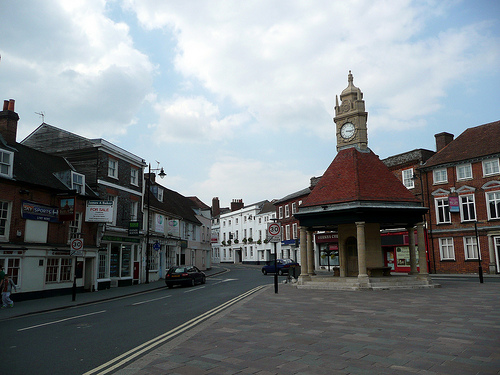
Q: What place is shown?
A: It is a city.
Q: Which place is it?
A: It is a city.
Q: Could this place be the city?
A: Yes, it is the city.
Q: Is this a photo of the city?
A: Yes, it is showing the city.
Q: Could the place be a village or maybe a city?
A: It is a city.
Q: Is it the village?
A: No, it is the city.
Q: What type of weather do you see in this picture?
A: It is cloudy.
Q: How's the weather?
A: It is cloudy.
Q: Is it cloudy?
A: Yes, it is cloudy.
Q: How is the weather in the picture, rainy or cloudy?
A: It is cloudy.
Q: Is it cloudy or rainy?
A: It is cloudy.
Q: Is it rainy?
A: No, it is cloudy.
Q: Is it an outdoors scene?
A: Yes, it is outdoors.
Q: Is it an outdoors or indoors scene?
A: It is outdoors.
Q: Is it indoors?
A: No, it is outdoors.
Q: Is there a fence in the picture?
A: No, there are no fences.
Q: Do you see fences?
A: No, there are no fences.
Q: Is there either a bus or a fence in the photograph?
A: No, there are no fences or buses.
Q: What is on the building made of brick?
A: The sign is on the building.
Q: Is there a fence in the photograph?
A: No, there are no fences.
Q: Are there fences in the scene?
A: No, there are no fences.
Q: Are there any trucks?
A: No, there are no trucks.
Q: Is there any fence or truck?
A: No, there are no trucks or fences.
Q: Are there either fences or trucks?
A: No, there are no trucks or fences.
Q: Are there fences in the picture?
A: No, there are no fences.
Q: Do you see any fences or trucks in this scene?
A: No, there are no fences or trucks.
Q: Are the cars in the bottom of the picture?
A: Yes, the cars are in the bottom of the image.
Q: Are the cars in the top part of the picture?
A: No, the cars are in the bottom of the image.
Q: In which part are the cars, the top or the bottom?
A: The cars are in the bottom of the image.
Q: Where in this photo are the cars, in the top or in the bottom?
A: The cars are in the bottom of the image.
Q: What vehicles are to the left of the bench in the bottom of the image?
A: The vehicles are cars.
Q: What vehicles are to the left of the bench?
A: The vehicles are cars.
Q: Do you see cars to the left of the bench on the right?
A: Yes, there are cars to the left of the bench.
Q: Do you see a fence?
A: No, there are no fences.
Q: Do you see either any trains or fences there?
A: No, there are no fences or trains.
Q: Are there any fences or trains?
A: No, there are no fences or trains.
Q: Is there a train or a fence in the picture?
A: No, there are no fences or trains.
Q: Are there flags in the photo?
A: No, there are no flags.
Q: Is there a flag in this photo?
A: No, there are no flags.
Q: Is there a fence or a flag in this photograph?
A: No, there are no flags or fences.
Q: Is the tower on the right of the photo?
A: Yes, the tower is on the right of the image.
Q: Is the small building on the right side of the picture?
A: Yes, the tower is on the right of the image.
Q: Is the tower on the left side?
A: No, the tower is on the right of the image.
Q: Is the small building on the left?
A: No, the tower is on the right of the image.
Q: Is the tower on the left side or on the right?
A: The tower is on the right of the image.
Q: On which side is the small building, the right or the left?
A: The tower is on the right of the image.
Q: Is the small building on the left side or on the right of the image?
A: The tower is on the right of the image.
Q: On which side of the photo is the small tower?
A: The tower is on the right of the image.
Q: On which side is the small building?
A: The tower is on the right of the image.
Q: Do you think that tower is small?
A: Yes, the tower is small.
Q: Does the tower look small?
A: Yes, the tower is small.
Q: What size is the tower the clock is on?
A: The tower is small.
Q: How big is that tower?
A: The tower is small.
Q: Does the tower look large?
A: No, the tower is small.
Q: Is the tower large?
A: No, the tower is small.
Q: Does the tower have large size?
A: No, the tower is small.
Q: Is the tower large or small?
A: The tower is small.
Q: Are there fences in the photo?
A: No, there are no fences.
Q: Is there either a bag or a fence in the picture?
A: No, there are no fences or bags.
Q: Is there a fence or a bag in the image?
A: No, there are no fences or bags.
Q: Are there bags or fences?
A: No, there are no fences or bags.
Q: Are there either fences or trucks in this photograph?
A: No, there are no fences or trucks.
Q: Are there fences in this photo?
A: No, there are no fences.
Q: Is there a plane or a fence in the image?
A: No, there are no fences or airplanes.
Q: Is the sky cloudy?
A: Yes, the sky is cloudy.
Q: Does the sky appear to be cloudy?
A: Yes, the sky is cloudy.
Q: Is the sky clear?
A: No, the sky is cloudy.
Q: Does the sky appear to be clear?
A: No, the sky is cloudy.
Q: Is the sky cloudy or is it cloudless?
A: The sky is cloudy.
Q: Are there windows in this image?
A: Yes, there are windows.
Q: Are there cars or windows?
A: Yes, there are windows.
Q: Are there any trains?
A: No, there are no trains.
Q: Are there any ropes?
A: No, there are no ropes.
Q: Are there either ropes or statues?
A: No, there are no ropes or statues.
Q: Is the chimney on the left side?
A: Yes, the chimney is on the left of the image.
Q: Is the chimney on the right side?
A: No, the chimney is on the left of the image.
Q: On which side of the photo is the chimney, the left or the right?
A: The chimney is on the left of the image.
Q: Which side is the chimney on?
A: The chimney is on the left of the image.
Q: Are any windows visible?
A: Yes, there are windows.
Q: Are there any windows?
A: Yes, there are windows.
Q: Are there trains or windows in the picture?
A: Yes, there are windows.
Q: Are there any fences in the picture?
A: No, there are no fences.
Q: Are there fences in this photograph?
A: No, there are no fences.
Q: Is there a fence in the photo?
A: No, there are no fences.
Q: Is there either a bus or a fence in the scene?
A: No, there are no fences or buses.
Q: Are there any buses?
A: No, there are no buses.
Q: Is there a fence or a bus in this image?
A: No, there are no buses or fences.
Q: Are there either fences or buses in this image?
A: No, there are no buses or fences.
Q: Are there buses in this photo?
A: No, there are no buses.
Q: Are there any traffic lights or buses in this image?
A: No, there are no buses or traffic lights.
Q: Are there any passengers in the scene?
A: No, there are no passengers.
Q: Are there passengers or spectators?
A: No, there are no passengers or spectators.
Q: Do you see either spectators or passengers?
A: No, there are no passengers or spectators.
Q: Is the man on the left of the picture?
A: Yes, the man is on the left of the image.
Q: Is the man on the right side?
A: No, the man is on the left of the image.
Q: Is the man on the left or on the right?
A: The man is on the left of the image.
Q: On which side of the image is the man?
A: The man is on the left of the image.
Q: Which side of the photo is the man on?
A: The man is on the left of the image.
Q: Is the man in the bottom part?
A: Yes, the man is in the bottom of the image.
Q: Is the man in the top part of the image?
A: No, the man is in the bottom of the image.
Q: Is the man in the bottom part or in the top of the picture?
A: The man is in the bottom of the image.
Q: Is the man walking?
A: Yes, the man is walking.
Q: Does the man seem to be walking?
A: Yes, the man is walking.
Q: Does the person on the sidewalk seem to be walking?
A: Yes, the man is walking.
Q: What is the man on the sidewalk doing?
A: The man is walking.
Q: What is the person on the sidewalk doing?
A: The man is walking.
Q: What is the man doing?
A: The man is walking.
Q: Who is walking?
A: The man is walking.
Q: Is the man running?
A: No, the man is walking.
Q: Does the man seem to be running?
A: No, the man is walking.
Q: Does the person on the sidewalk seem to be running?
A: No, the man is walking.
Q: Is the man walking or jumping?
A: The man is walking.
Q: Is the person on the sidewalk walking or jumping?
A: The man is walking.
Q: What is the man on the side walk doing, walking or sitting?
A: The man is walking.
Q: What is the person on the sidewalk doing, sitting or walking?
A: The man is walking.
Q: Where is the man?
A: The man is on the sidewalk.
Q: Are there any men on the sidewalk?
A: Yes, there is a man on the sidewalk.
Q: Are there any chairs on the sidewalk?
A: No, there is a man on the sidewalk.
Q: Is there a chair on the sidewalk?
A: No, there is a man on the sidewalk.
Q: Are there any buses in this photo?
A: No, there are no buses.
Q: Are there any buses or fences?
A: No, there are no buses or fences.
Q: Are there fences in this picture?
A: No, there are no fences.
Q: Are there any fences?
A: No, there are no fences.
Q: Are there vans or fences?
A: No, there are no fences or vans.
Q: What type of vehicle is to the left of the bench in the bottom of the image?
A: The vehicle is a car.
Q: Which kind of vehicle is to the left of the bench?
A: The vehicle is a car.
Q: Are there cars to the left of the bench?
A: Yes, there is a car to the left of the bench.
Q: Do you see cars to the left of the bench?
A: Yes, there is a car to the left of the bench.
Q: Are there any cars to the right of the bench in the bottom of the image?
A: No, the car is to the left of the bench.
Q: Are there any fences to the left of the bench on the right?
A: No, there is a car to the left of the bench.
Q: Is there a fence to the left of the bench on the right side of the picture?
A: No, there is a car to the left of the bench.